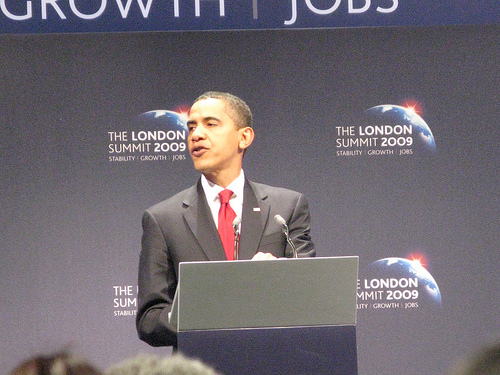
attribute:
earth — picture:
[353, 97, 455, 167]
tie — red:
[205, 187, 249, 248]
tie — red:
[215, 190, 237, 261]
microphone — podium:
[270, 214, 308, 261]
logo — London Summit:
[322, 115, 425, 161]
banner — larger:
[1, 0, 499, 35]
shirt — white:
[198, 170, 245, 235]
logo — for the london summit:
[71, 98, 229, 194]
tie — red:
[204, 190, 261, 265]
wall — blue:
[47, 65, 442, 370]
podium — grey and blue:
[162, 239, 379, 369]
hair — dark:
[198, 90, 256, 127]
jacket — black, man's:
[135, 170, 315, 346]